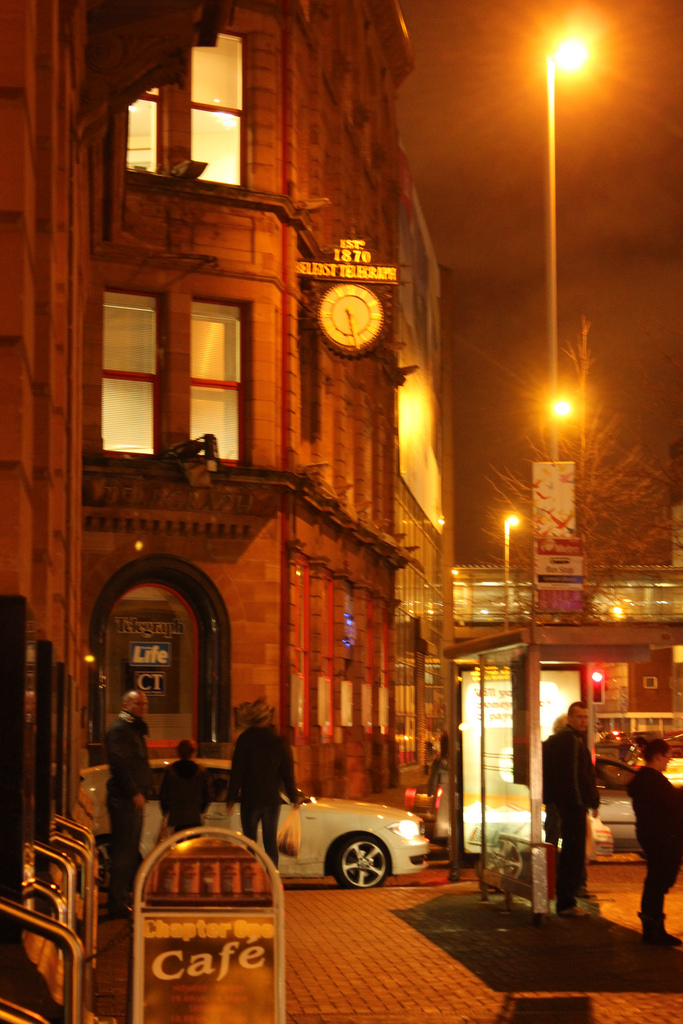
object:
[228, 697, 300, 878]
man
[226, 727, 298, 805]
jacket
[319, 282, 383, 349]
clock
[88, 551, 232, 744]
archedwindow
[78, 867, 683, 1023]
pavers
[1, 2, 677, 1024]
downtown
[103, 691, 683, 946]
people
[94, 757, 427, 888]
cars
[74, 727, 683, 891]
street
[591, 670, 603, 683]
trafficlight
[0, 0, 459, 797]
buildings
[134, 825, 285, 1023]
sign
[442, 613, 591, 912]
busstop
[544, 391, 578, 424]
streetlights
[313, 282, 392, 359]
clock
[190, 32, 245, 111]
window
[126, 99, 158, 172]
window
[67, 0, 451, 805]
building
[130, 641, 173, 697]
advertising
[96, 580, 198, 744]
window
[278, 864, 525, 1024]
walkway